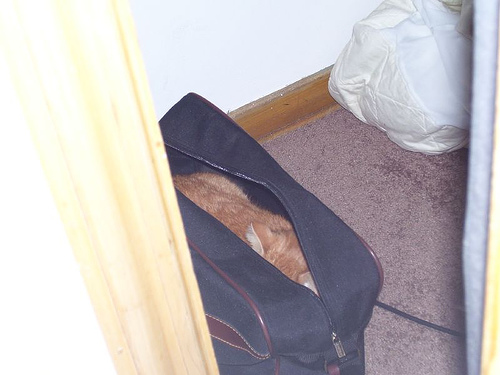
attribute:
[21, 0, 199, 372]
door frame — brown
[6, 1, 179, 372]
trim — wooden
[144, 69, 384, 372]
bag — black 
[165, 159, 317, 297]
cat — orange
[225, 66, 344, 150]
border — dark brown, wall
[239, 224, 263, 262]
ears — orange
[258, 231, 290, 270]
ears — orange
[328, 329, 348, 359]
zipper — bronze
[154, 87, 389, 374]
bag — black , dark blue, blue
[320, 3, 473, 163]
bag — white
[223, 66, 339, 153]
board — brown, wooden, skirting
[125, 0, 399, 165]
wall — white